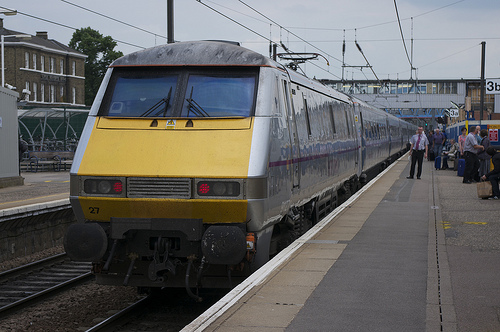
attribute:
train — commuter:
[58, 44, 434, 292]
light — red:
[189, 178, 214, 201]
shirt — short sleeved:
[408, 132, 428, 150]